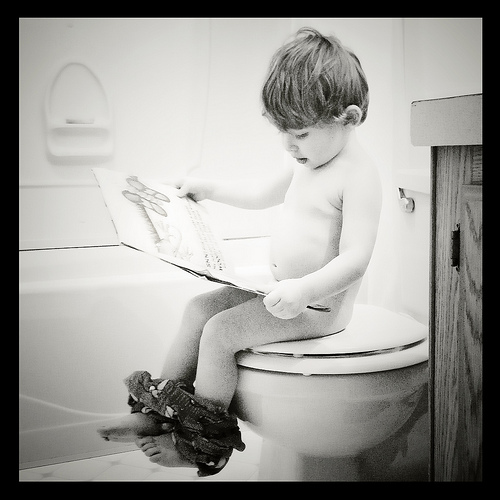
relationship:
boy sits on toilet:
[97, 28, 387, 469] [231, 175, 428, 480]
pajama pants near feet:
[120, 371, 241, 470] [114, 382, 235, 477]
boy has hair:
[97, 28, 387, 469] [252, 24, 374, 134]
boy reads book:
[97, 28, 387, 469] [83, 159, 275, 296]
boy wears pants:
[97, 28, 387, 469] [120, 365, 252, 478]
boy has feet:
[97, 28, 387, 469] [86, 402, 210, 468]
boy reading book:
[93, 28, 387, 468] [95, 155, 327, 312]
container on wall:
[38, 51, 124, 163] [19, 24, 381, 227]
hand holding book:
[264, 277, 302, 317] [95, 155, 327, 312]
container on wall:
[38, 51, 124, 163] [10, 10, 422, 265]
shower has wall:
[17, 15, 289, 260] [10, 10, 422, 265]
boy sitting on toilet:
[93, 28, 387, 468] [231, 175, 428, 480]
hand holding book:
[264, 277, 302, 317] [80, 144, 325, 340]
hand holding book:
[171, 171, 209, 203] [80, 144, 325, 340]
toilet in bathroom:
[231, 175, 428, 480] [21, 24, 484, 484]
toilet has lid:
[20, 11, 484, 479] [239, 302, 435, 370]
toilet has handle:
[20, 11, 484, 479] [395, 186, 415, 212]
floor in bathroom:
[44, 458, 186, 491] [21, 24, 484, 484]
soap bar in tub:
[65, 113, 98, 126] [49, 67, 121, 177]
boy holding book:
[97, 28, 387, 469] [95, 155, 327, 312]